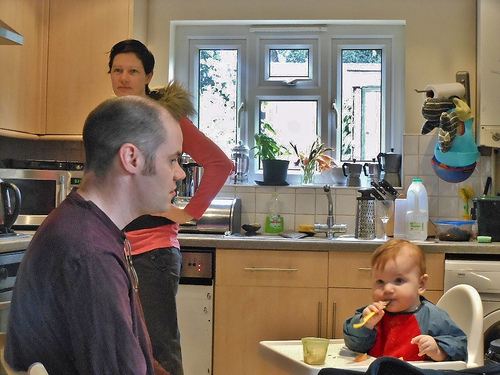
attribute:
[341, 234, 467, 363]
baby — a redhead, chubby, redhead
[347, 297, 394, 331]
spoon — yellow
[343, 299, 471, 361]
shirt — red, grey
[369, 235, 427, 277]
hair — red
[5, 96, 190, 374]
man — sitting, balding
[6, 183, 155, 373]
shirt — purple, maroon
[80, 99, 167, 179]
hair — short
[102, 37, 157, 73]
hair — black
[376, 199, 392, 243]
glass — clear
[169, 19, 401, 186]
window — closed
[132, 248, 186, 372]
pants — black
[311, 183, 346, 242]
faucet — chrome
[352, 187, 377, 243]
cheese grater — metal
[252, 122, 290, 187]
potted plant — green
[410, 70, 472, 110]
paper towel holder — metal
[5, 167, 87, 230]
microwave — aluminum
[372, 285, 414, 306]
cheeks — chubby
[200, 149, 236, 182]
elbow — bent